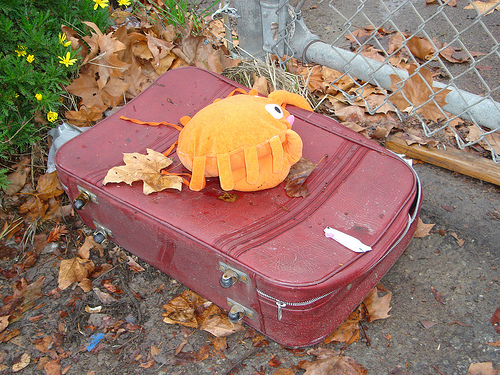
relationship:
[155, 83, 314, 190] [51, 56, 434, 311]
stuffed animal on top of suitcase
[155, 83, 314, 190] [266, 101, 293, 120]
stuffed animal has eye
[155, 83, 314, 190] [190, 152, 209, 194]
stuffed animal has leg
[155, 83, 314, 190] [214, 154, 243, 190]
stuffed animal has leg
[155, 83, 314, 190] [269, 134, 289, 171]
stuffed animal has leg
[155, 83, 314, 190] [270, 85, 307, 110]
stuffed animal has leg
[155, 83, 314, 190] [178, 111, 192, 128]
stuffed animal has leg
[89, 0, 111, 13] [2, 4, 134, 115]
flower in grass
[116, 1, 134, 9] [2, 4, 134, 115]
flower in grass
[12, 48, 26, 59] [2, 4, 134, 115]
flower in grass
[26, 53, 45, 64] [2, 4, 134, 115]
flower in grass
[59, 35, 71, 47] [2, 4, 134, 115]
flower in grass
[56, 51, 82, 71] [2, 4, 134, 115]
flower in grass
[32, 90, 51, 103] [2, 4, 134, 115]
flower in grass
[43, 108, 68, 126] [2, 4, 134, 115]
flower in grass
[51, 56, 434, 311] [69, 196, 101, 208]
suitcase has wheel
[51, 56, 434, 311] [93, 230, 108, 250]
suitcase has wheel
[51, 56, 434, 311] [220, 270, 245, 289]
suitcase has wheel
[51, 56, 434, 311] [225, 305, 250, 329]
suitcase has wheel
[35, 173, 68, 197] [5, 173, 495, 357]
leaf laying on ground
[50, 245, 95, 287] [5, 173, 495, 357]
leaf laying on ground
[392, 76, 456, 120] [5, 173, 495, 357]
leaf laying on ground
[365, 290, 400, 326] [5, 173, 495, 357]
leaf laying on ground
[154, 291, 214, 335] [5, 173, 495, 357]
leaf laying on ground